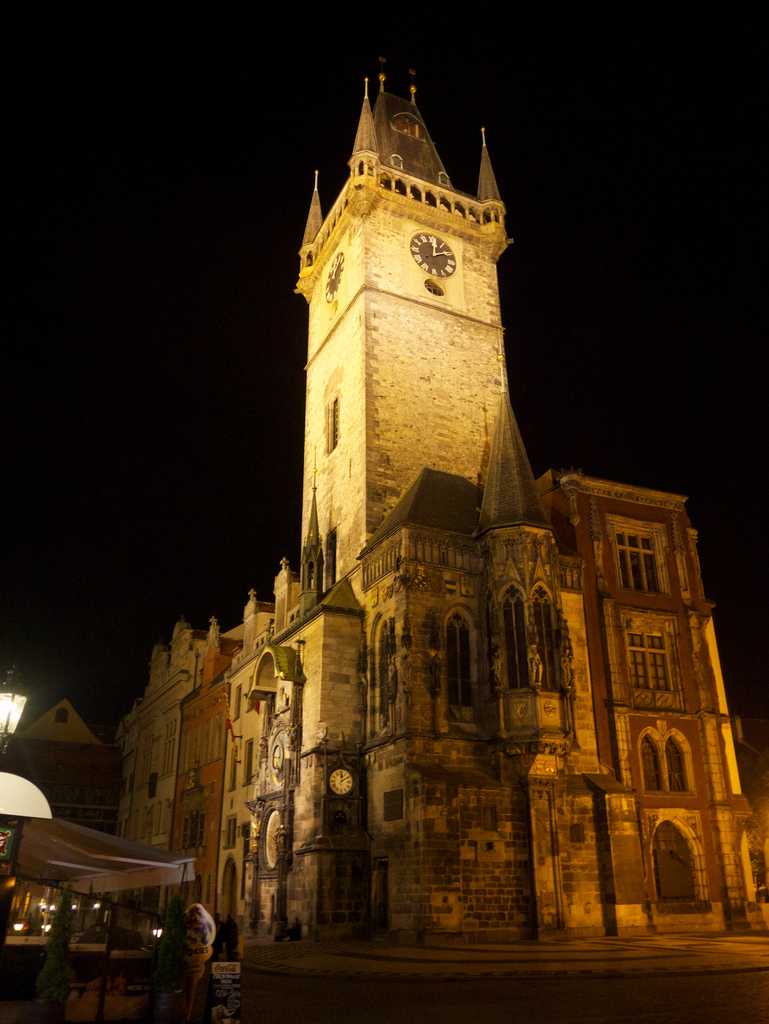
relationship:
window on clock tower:
[309, 388, 355, 469] [291, 296, 511, 502]